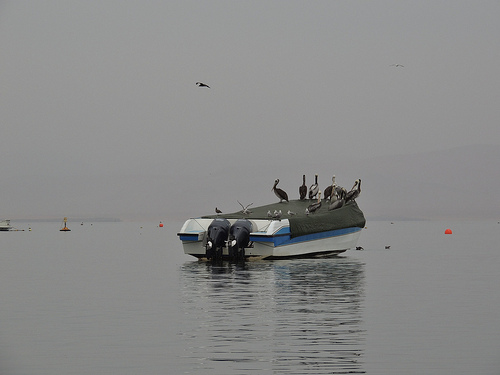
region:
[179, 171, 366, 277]
covered boat in the water with pelicans on top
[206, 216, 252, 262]
two motors on the back of a boat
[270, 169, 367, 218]
pelicans sitting on a motor boat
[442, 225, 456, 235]
red round buoy in the water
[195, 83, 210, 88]
seagul flying in the sky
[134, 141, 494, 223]
fog covered hill by the water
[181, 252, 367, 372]
reflection of the boat in the water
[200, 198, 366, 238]
black cover on the motor boat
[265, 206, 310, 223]
sea gulls sitting on a motor boat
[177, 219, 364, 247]
blue stripe on the motor boat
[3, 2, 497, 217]
cloud cover in sky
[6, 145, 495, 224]
haze in front of mountain range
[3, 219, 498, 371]
surface of calm water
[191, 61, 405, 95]
two birds in sky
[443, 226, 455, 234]
orange bubble in water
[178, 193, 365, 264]
covered boat on water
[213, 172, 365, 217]
birds on boat cover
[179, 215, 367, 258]
blue and white side of boat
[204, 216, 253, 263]
backs of two motors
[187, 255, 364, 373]
reflection on water surface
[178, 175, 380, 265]
this is a boat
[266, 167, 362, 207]
these are birds on the boat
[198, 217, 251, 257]
these are two engines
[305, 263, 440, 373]
this is the water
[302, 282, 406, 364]
the water is calm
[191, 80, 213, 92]
the bird is on air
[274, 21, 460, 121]
this is the sky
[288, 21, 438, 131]
the sky is grey in color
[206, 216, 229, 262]
the engine is black in color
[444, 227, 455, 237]
the ball is orange in color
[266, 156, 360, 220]
group of pelicans on a boat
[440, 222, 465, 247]
orange bouy in the water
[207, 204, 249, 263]
two engines on the back of a boat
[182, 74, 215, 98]
bird flying in the sky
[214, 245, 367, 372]
reflection of a boat in the water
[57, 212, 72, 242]
tall bouy in the water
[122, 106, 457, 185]
hazy sky with the outline of a hill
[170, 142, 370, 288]
boat covered with birds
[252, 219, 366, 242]
blue stripe on the side of a boat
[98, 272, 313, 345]
calm body of water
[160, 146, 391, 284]
a boat floating in water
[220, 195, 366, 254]
a boat covered with a black tarp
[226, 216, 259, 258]
a black motor on a boat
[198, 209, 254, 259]
two motors on a boat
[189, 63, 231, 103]
a bird flying in the sky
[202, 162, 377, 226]
several birds on a boat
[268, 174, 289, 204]
a bird with a long beak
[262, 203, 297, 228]
four birds sitting on a boat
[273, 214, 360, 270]
a blue and white boat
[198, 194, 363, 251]
a tarp covering a boat